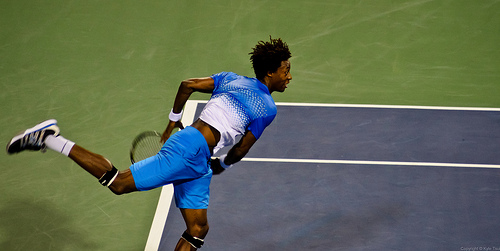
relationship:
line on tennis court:
[135, 98, 197, 250] [144, 98, 500, 237]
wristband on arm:
[169, 107, 183, 119] [155, 73, 232, 144]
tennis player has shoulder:
[5, 34, 299, 250] [254, 101, 284, 124]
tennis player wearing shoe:
[5, 34, 299, 250] [8, 115, 64, 155]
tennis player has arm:
[5, 34, 299, 250] [212, 108, 279, 177]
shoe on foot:
[8, 115, 64, 155] [8, 114, 68, 162]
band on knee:
[183, 229, 209, 248] [179, 217, 213, 239]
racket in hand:
[129, 129, 169, 163] [161, 119, 188, 138]